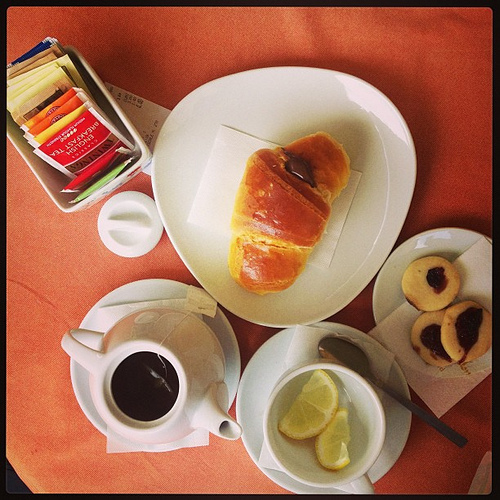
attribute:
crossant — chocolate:
[214, 109, 359, 301]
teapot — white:
[64, 309, 234, 441]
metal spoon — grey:
[316, 333, 471, 450]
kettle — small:
[56, 290, 241, 490]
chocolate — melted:
[288, 150, 311, 186]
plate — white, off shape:
[149, 65, 418, 330]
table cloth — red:
[427, 17, 476, 177]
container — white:
[4, 39, 151, 212]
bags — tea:
[4, 40, 138, 204]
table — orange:
[0, 22, 482, 492]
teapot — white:
[59, 304, 242, 442]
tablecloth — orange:
[11, 10, 481, 493]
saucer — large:
[150, 63, 418, 328]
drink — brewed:
[110, 350, 177, 422]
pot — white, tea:
[58, 307, 243, 443]